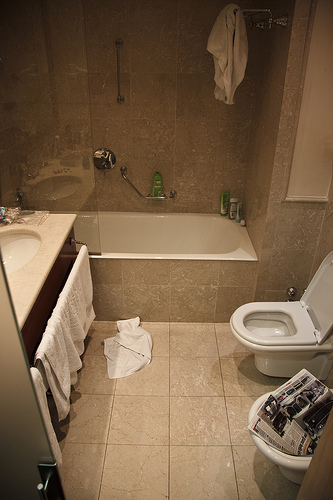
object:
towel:
[96, 318, 154, 383]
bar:
[33, 232, 95, 423]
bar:
[115, 38, 126, 102]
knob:
[92, 146, 116, 172]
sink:
[0, 223, 41, 278]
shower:
[0, 0, 296, 255]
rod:
[27, 243, 96, 401]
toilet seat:
[230, 299, 317, 346]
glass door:
[1, 1, 102, 255]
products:
[227, 197, 247, 227]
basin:
[248, 389, 333, 486]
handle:
[36, 462, 59, 500]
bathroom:
[0, 0, 333, 500]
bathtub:
[74, 212, 259, 323]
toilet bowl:
[229, 253, 333, 379]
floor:
[60, 317, 300, 498]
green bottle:
[147, 167, 166, 198]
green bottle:
[220, 190, 230, 217]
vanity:
[3, 207, 94, 445]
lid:
[300, 251, 333, 346]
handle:
[112, 36, 125, 104]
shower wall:
[2, 3, 293, 210]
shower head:
[239, 7, 275, 30]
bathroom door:
[0, 253, 67, 500]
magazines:
[248, 366, 333, 455]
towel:
[29, 243, 97, 464]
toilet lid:
[300, 251, 333, 342]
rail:
[117, 164, 176, 201]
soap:
[228, 195, 238, 220]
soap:
[236, 203, 241, 223]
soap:
[241, 219, 246, 226]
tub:
[61, 208, 257, 319]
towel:
[205, 2, 249, 108]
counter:
[0, 204, 77, 363]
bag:
[0, 206, 50, 226]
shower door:
[0, 0, 102, 254]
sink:
[21, 172, 85, 207]